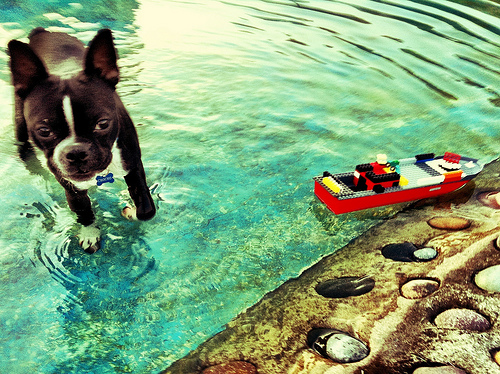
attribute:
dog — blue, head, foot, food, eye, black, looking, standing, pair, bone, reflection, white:
[15, 12, 193, 251]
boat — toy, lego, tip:
[266, 127, 481, 240]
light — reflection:
[199, 37, 254, 76]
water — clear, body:
[190, 20, 349, 189]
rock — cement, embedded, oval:
[298, 234, 409, 317]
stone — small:
[386, 250, 431, 276]